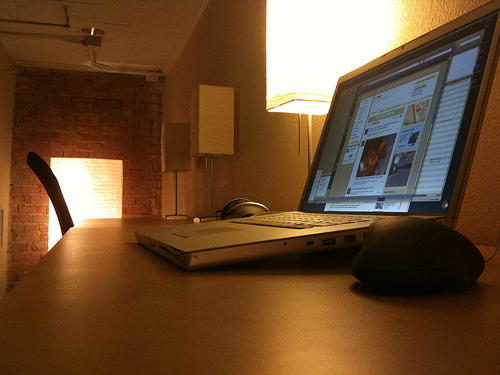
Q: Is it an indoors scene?
A: Yes, it is indoors.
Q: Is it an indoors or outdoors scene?
A: It is indoors.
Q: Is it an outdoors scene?
A: No, it is indoors.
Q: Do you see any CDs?
A: No, there are no cds.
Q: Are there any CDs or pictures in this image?
A: No, there are no CDs or pictures.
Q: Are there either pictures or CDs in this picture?
A: No, there are no CDs or pictures.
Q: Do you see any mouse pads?
A: Yes, there is a mouse pad.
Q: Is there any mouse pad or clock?
A: Yes, there is a mouse pad.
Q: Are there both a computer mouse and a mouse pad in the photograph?
A: Yes, there are both a mouse pad and a computer mouse.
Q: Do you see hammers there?
A: No, there are no hammers.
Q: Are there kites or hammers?
A: No, there are no hammers or kites.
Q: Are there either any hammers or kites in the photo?
A: No, there are no hammers or kites.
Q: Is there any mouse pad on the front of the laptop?
A: Yes, there is a mouse pad on the front of the laptop.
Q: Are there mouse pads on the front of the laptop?
A: Yes, there is a mouse pad on the front of the laptop.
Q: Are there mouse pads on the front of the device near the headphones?
A: Yes, there is a mouse pad on the front of the laptop.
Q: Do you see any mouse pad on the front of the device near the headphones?
A: Yes, there is a mouse pad on the front of the laptop.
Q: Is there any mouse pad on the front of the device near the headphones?
A: Yes, there is a mouse pad on the front of the laptop.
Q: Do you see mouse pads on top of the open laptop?
A: Yes, there is a mouse pad on top of the laptop.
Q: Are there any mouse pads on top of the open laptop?
A: Yes, there is a mouse pad on top of the laptop.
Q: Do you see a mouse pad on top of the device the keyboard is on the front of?
A: Yes, there is a mouse pad on top of the laptop.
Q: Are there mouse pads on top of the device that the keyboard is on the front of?
A: Yes, there is a mouse pad on top of the laptop.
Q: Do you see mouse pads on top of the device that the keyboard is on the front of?
A: Yes, there is a mouse pad on top of the laptop.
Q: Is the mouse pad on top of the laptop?
A: Yes, the mouse pad is on top of the laptop.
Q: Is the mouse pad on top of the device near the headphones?
A: Yes, the mouse pad is on top of the laptop.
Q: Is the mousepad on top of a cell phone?
A: No, the mousepad is on top of the laptop.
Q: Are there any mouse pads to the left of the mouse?
A: Yes, there is a mouse pad to the left of the mouse.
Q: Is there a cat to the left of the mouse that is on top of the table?
A: No, there is a mouse pad to the left of the computer mouse.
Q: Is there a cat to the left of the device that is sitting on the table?
A: No, there is a mouse pad to the left of the computer mouse.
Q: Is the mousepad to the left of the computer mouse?
A: Yes, the mousepad is to the left of the computer mouse.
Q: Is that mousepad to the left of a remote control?
A: No, the mousepad is to the left of the computer mouse.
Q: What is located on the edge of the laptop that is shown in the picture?
A: The mouse pad is on the edge of the laptop.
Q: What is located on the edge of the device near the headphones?
A: The mouse pad is on the edge of the laptop.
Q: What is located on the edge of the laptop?
A: The mouse pad is on the edge of the laptop.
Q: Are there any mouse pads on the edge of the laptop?
A: Yes, there is a mouse pad on the edge of the laptop.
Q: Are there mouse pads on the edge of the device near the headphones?
A: Yes, there is a mouse pad on the edge of the laptop.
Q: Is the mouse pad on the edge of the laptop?
A: Yes, the mouse pad is on the edge of the laptop.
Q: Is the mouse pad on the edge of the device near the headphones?
A: Yes, the mouse pad is on the edge of the laptop.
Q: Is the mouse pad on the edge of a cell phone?
A: No, the mouse pad is on the edge of the laptop.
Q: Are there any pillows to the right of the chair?
A: No, there is a mouse pad to the right of the chair.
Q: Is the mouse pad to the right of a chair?
A: Yes, the mouse pad is to the right of a chair.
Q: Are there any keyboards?
A: Yes, there is a keyboard.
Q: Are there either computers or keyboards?
A: Yes, there is a keyboard.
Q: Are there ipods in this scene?
A: No, there are no ipods.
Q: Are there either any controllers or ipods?
A: No, there are no ipods or controllers.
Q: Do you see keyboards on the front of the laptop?
A: Yes, there is a keyboard on the front of the laptop.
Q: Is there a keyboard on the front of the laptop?
A: Yes, there is a keyboard on the front of the laptop.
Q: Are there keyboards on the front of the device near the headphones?
A: Yes, there is a keyboard on the front of the laptop.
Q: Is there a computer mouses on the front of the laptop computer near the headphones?
A: No, there is a keyboard on the front of the laptop.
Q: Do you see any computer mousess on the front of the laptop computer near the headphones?
A: No, there is a keyboard on the front of the laptop.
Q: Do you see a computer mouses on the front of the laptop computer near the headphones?
A: No, there is a keyboard on the front of the laptop.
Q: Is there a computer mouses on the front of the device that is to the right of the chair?
A: No, there is a keyboard on the front of the laptop.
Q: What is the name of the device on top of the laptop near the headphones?
A: The device is a keyboard.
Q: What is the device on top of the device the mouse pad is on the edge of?
A: The device is a keyboard.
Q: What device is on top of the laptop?
A: The device is a keyboard.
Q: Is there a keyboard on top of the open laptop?
A: Yes, there is a keyboard on top of the laptop.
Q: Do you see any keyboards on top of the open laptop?
A: Yes, there is a keyboard on top of the laptop.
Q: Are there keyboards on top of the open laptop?
A: Yes, there is a keyboard on top of the laptop.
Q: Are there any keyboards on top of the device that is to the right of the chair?
A: Yes, there is a keyboard on top of the laptop.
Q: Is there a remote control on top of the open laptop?
A: No, there is a keyboard on top of the laptop.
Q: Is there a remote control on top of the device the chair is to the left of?
A: No, there is a keyboard on top of the laptop.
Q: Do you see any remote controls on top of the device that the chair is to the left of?
A: No, there is a keyboard on top of the laptop.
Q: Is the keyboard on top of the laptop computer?
A: Yes, the keyboard is on top of the laptop computer.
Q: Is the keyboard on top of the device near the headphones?
A: Yes, the keyboard is on top of the laptop computer.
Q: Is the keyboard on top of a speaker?
A: No, the keyboard is on top of the laptop computer.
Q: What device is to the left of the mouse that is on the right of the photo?
A: The device is a keyboard.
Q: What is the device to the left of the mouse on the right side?
A: The device is a keyboard.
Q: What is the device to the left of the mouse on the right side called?
A: The device is a keyboard.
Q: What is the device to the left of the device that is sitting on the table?
A: The device is a keyboard.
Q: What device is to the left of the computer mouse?
A: The device is a keyboard.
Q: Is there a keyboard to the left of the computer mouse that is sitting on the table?
A: Yes, there is a keyboard to the left of the mouse.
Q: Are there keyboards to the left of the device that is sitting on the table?
A: Yes, there is a keyboard to the left of the mouse.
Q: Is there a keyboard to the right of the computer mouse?
A: No, the keyboard is to the left of the computer mouse.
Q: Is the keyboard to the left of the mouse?
A: Yes, the keyboard is to the left of the mouse.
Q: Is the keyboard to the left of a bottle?
A: No, the keyboard is to the left of the mouse.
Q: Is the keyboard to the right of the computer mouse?
A: No, the keyboard is to the left of the computer mouse.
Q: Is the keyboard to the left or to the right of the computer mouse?
A: The keyboard is to the left of the computer mouse.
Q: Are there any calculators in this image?
A: No, there are no calculators.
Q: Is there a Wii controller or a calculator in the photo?
A: No, there are no calculators or Wii controllers.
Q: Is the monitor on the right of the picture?
A: Yes, the monitor is on the right of the image.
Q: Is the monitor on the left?
A: No, the monitor is on the right of the image.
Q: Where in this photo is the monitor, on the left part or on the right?
A: The monitor is on the right of the image.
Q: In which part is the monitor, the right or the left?
A: The monitor is on the right of the image.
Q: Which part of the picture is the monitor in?
A: The monitor is on the right of the image.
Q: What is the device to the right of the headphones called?
A: The device is a monitor.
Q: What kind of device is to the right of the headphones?
A: The device is a monitor.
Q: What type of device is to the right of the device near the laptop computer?
A: The device is a monitor.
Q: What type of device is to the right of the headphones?
A: The device is a monitor.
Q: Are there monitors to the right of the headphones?
A: Yes, there is a monitor to the right of the headphones.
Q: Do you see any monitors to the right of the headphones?
A: Yes, there is a monitor to the right of the headphones.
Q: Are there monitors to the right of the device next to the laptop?
A: Yes, there is a monitor to the right of the headphones.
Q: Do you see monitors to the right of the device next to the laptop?
A: Yes, there is a monitor to the right of the headphones.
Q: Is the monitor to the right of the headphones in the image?
A: Yes, the monitor is to the right of the headphones.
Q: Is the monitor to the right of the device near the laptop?
A: Yes, the monitor is to the right of the headphones.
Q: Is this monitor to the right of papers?
A: No, the monitor is to the right of the headphones.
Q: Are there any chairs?
A: Yes, there is a chair.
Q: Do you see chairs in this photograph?
A: Yes, there is a chair.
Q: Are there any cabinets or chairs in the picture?
A: Yes, there is a chair.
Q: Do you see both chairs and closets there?
A: No, there is a chair but no closets.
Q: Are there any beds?
A: No, there are no beds.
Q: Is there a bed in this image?
A: No, there are no beds.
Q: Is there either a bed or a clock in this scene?
A: No, there are no beds or clocks.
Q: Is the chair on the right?
A: No, the chair is on the left of the image.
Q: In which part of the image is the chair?
A: The chair is on the left of the image.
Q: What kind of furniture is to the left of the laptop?
A: The piece of furniture is a chair.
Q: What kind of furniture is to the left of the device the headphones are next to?
A: The piece of furniture is a chair.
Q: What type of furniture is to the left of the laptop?
A: The piece of furniture is a chair.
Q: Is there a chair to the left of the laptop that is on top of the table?
A: Yes, there is a chair to the left of the laptop.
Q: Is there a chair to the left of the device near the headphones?
A: Yes, there is a chair to the left of the laptop.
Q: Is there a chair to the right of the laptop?
A: No, the chair is to the left of the laptop.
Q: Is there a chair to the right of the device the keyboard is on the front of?
A: No, the chair is to the left of the laptop.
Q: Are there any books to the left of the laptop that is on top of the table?
A: No, there is a chair to the left of the laptop.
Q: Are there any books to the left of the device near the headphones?
A: No, there is a chair to the left of the laptop.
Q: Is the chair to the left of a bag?
A: No, the chair is to the left of the laptop.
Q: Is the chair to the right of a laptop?
A: No, the chair is to the left of a laptop.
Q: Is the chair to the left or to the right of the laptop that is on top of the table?
A: The chair is to the left of the laptop.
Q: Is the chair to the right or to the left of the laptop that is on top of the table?
A: The chair is to the left of the laptop.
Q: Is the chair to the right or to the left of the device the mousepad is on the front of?
A: The chair is to the left of the laptop.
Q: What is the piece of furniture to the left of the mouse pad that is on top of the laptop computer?
A: The piece of furniture is a chair.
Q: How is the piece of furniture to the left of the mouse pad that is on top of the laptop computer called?
A: The piece of furniture is a chair.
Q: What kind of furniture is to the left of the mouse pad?
A: The piece of furniture is a chair.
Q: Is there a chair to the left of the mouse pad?
A: Yes, there is a chair to the left of the mouse pad.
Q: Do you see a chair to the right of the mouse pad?
A: No, the chair is to the left of the mouse pad.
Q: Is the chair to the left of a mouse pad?
A: Yes, the chair is to the left of a mouse pad.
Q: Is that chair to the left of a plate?
A: No, the chair is to the left of a mouse pad.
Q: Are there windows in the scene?
A: Yes, there is a window.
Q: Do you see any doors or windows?
A: Yes, there is a window.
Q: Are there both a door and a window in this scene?
A: No, there is a window but no doors.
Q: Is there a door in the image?
A: No, there are no doors.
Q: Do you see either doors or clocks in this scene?
A: No, there are no doors or clocks.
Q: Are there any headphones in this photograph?
A: Yes, there are headphones.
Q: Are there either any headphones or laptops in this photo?
A: Yes, there are headphones.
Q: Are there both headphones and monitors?
A: Yes, there are both headphones and a monitor.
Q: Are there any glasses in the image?
A: No, there are no glasses.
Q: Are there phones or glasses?
A: No, there are no glasses or phones.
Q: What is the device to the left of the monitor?
A: The device is headphones.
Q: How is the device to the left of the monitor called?
A: The device is headphones.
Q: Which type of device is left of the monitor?
A: The device is headphones.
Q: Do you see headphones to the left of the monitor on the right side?
A: Yes, there are headphones to the left of the monitor.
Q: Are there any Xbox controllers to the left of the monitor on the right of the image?
A: No, there are headphones to the left of the monitor.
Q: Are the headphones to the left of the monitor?
A: Yes, the headphones are to the left of the monitor.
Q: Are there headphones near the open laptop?
A: Yes, there are headphones near the laptop.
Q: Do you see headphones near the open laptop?
A: Yes, there are headphones near the laptop.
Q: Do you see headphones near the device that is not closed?
A: Yes, there are headphones near the laptop.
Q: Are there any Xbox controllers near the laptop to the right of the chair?
A: No, there are headphones near the laptop computer.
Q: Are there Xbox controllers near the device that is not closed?
A: No, there are headphones near the laptop computer.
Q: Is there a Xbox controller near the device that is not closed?
A: No, there are headphones near the laptop computer.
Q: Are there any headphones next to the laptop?
A: Yes, there are headphones next to the laptop.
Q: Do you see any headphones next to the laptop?
A: Yes, there are headphones next to the laptop.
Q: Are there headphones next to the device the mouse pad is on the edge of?
A: Yes, there are headphones next to the laptop.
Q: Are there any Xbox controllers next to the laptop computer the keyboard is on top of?
A: No, there are headphones next to the laptop.